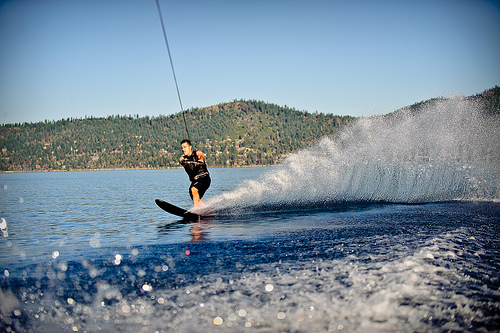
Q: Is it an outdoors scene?
A: Yes, it is outdoors.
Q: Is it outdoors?
A: Yes, it is outdoors.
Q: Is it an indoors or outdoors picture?
A: It is outdoors.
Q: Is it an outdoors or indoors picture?
A: It is outdoors.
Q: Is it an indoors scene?
A: No, it is outdoors.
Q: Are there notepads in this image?
A: No, there are no notepads.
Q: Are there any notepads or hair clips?
A: No, there are no notepads or hair clips.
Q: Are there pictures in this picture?
A: No, there are no pictures.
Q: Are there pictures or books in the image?
A: No, there are no pictures or books.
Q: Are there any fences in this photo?
A: No, there are no fences.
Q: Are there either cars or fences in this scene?
A: No, there are no fences or cars.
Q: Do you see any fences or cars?
A: No, there are no fences or cars.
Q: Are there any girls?
A: No, there are no girls.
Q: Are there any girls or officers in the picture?
A: No, there are no girls or officers.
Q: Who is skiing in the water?
A: The man is skiing in the water.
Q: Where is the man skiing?
A: The man is skiing in the water.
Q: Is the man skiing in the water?
A: Yes, the man is skiing in the water.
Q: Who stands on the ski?
A: The man stands on the ski.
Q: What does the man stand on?
A: The man stands on the ski.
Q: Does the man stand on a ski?
A: Yes, the man stands on a ski.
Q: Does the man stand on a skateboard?
A: No, the man stands on a ski.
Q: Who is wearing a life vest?
A: The man is wearing a life vest.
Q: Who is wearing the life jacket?
A: The man is wearing a life vest.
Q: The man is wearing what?
A: The man is wearing a life vest.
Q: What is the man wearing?
A: The man is wearing a life vest.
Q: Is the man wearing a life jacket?
A: Yes, the man is wearing a life jacket.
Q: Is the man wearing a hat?
A: No, the man is wearing a life jacket.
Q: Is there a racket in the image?
A: No, there are no rackets.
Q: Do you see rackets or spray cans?
A: No, there are no rackets or spray cans.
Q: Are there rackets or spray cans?
A: No, there are no rackets or spray cans.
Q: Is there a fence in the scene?
A: No, there are no fences.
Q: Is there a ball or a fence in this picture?
A: No, there are no fences or balls.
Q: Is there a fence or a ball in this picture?
A: No, there are no fences or balls.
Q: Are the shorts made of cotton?
A: Yes, the shorts are made of cotton.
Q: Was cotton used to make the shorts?
A: Yes, the shorts are made of cotton.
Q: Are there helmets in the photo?
A: No, there are no helmets.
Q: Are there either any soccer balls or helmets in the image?
A: No, there are no helmets or soccer balls.